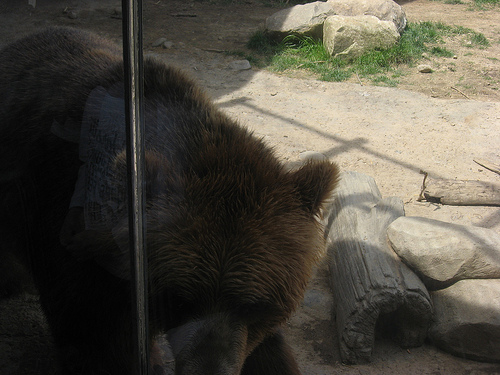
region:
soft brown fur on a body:
[175, 175, 254, 248]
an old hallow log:
[341, 231, 408, 353]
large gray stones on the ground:
[417, 216, 484, 340]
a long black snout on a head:
[174, 326, 247, 371]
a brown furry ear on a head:
[294, 161, 351, 206]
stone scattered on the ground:
[417, 49, 448, 74]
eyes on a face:
[169, 276, 264, 334]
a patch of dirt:
[464, 8, 489, 30]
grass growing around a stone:
[301, 43, 346, 69]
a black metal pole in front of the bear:
[111, 4, 161, 356]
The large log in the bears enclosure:
[320, 165, 431, 360]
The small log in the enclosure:
[412, 168, 499, 205]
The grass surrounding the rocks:
[245, 21, 487, 87]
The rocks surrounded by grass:
[263, 0, 406, 60]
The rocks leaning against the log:
[388, 211, 499, 361]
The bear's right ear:
[294, 155, 346, 214]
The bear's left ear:
[108, 150, 163, 200]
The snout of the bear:
[162, 314, 254, 373]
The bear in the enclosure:
[0, 21, 340, 371]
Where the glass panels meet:
[116, 1, 160, 373]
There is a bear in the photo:
[37, 82, 403, 372]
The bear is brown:
[56, 69, 378, 373]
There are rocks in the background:
[327, 186, 497, 326]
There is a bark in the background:
[233, 171, 447, 350]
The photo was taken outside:
[22, 13, 496, 354]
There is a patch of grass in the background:
[226, 9, 481, 108]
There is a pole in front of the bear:
[58, 52, 394, 366]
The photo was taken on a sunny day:
[54, 11, 496, 253]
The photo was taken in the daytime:
[27, 6, 498, 368]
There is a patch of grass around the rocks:
[276, 13, 495, 107]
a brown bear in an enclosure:
[3, 32, 339, 372]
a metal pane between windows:
[11, 2, 478, 365]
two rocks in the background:
[261, 0, 406, 82]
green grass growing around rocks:
[240, 3, 490, 89]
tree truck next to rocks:
[321, 162, 494, 360]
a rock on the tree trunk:
[327, 195, 453, 306]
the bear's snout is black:
[156, 310, 247, 371]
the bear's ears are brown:
[113, 142, 340, 218]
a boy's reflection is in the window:
[57, 17, 188, 287]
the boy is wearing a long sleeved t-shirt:
[65, 82, 189, 247]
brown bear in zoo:
[36, 5, 318, 366]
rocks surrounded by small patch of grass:
[247, 0, 429, 75]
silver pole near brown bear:
[127, 42, 173, 370]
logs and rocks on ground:
[331, 147, 491, 348]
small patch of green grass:
[256, 37, 316, 80]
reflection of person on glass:
[57, 43, 192, 322]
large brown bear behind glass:
[35, 56, 309, 365]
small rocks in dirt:
[147, 25, 179, 65]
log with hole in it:
[329, 153, 424, 353]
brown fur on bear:
[177, 150, 260, 283]